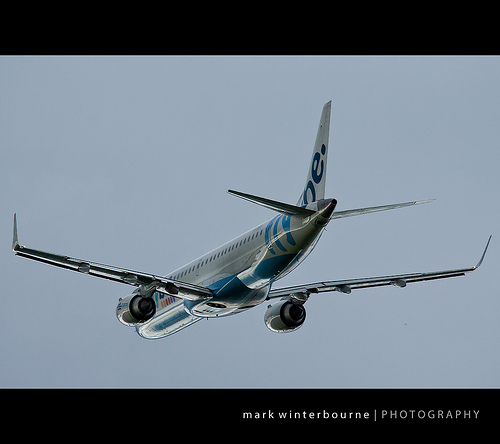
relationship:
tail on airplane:
[229, 97, 435, 224] [1, 95, 498, 335]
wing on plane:
[271, 233, 493, 297] [12, 100, 491, 338]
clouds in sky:
[319, 335, 482, 385] [6, 58, 488, 184]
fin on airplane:
[302, 99, 329, 206] [1, 95, 498, 335]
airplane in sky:
[1, 95, 498, 335] [0, 54, 500, 390]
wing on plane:
[330, 191, 440, 225] [12, 100, 491, 338]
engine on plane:
[114, 293, 156, 325] [12, 100, 491, 338]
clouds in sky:
[422, 346, 490, 377] [0, 54, 500, 390]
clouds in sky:
[5, 66, 496, 386] [0, 54, 500, 390]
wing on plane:
[8, 210, 215, 315] [0, 97, 487, 359]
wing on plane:
[265, 235, 495, 331] [12, 100, 491, 338]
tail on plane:
[298, 88, 338, 212] [12, 100, 491, 338]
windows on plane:
[238, 237, 244, 249] [12, 100, 491, 338]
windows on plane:
[231, 240, 235, 252] [12, 100, 491, 338]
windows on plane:
[258, 225, 263, 237] [12, 100, 491, 338]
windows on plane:
[254, 227, 257, 239] [12, 100, 491, 338]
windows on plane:
[211, 251, 215, 261] [12, 100, 491, 338]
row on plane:
[153, 294, 176, 306] [12, 100, 491, 338]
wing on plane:
[11, 212, 212, 300] [12, 100, 491, 338]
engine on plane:
[114, 293, 156, 325] [0, 97, 487, 359]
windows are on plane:
[161, 225, 265, 283] [12, 100, 491, 338]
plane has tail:
[12, 100, 491, 338] [296, 94, 346, 210]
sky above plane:
[0, 54, 500, 390] [0, 97, 487, 359]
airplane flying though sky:
[1, 95, 498, 335] [0, 54, 500, 390]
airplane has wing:
[1, 95, 498, 335] [8, 210, 215, 315]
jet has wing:
[44, 100, 489, 375] [250, 232, 496, 300]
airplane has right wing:
[1, 95, 498, 335] [265, 234, 492, 334]